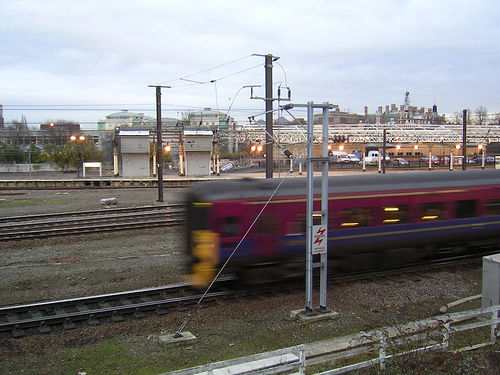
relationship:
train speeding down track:
[175, 167, 499, 288] [3, 281, 228, 333]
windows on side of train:
[295, 197, 500, 227] [175, 167, 499, 288]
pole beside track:
[288, 101, 342, 322] [3, 281, 228, 333]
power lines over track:
[4, 96, 499, 168] [3, 281, 228, 333]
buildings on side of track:
[4, 90, 499, 177] [3, 281, 228, 333]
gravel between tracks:
[3, 239, 181, 281] [3, 203, 197, 336]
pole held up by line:
[288, 101, 342, 322] [177, 162, 302, 332]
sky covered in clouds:
[1, 1, 499, 123] [41, 8, 305, 104]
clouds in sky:
[41, 8, 305, 104] [1, 1, 499, 123]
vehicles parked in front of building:
[333, 148, 496, 171] [268, 121, 499, 166]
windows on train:
[295, 197, 500, 227] [175, 167, 499, 288]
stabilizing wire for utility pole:
[176, 143, 304, 334] [290, 96, 337, 314]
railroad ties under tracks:
[3, 298, 238, 340] [3, 203, 197, 336]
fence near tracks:
[254, 304, 500, 374] [3, 203, 197, 336]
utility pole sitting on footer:
[290, 96, 337, 314] [291, 301, 339, 325]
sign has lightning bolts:
[311, 222, 328, 255] [313, 225, 327, 247]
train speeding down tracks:
[175, 167, 499, 288] [3, 203, 197, 336]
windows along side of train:
[295, 197, 500, 227] [175, 167, 499, 288]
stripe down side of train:
[279, 216, 500, 260] [175, 167, 499, 288]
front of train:
[174, 178, 221, 290] [175, 167, 499, 288]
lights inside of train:
[337, 204, 439, 229] [175, 167, 499, 288]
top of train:
[193, 166, 499, 200] [175, 167, 499, 288]